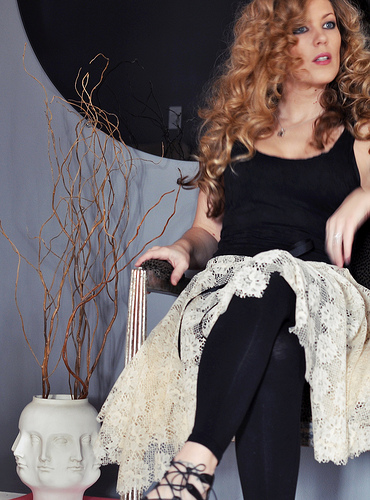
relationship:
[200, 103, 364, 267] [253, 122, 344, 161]
tank top with neck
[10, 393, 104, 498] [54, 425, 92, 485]
planter with face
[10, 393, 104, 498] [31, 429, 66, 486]
planter with face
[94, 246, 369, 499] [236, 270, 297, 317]
shawl on knee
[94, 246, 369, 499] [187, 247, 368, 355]
shawl on lap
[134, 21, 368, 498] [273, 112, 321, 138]
woman wearing necklace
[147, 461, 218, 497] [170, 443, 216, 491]
shoes ties on ankle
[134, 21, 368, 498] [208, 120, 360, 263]
woman wearing tank top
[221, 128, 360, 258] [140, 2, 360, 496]
woman wearing top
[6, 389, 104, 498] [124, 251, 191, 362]
white vase beside chair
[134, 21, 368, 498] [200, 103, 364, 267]
woman wearing tank top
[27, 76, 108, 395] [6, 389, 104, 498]
curely sticks in white vase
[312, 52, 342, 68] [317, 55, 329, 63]
pink lips and teeth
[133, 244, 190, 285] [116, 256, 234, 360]
hand on armrest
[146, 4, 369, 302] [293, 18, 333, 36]
woman wearing makeup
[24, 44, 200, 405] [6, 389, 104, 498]
branches in white vase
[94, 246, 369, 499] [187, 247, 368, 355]
shawl across lap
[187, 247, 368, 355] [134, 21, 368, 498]
lap of woman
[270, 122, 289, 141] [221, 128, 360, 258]
necklace of woman